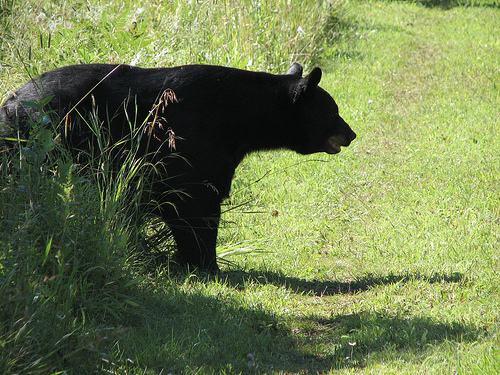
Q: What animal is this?
A: Bear.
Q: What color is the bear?
A: Black.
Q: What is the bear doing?
A: Standing.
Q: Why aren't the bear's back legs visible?
A: Hidden by grass.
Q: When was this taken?
A: Daytime.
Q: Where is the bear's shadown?
A: On the ground.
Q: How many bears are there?
A: 1.